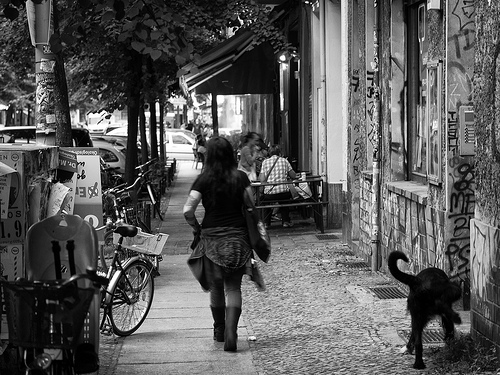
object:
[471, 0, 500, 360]
wall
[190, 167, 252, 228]
black shirt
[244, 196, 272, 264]
purse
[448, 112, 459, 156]
graffiti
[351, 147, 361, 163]
graffiti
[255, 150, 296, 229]
person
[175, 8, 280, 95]
awning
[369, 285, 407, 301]
drainage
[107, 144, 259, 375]
porch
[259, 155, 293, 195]
shirt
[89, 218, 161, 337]
bike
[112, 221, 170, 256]
basket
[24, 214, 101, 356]
seat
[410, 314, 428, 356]
leg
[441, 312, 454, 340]
leg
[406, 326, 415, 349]
leg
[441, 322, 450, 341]
leg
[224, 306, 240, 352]
boot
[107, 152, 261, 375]
sidewalk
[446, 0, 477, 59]
graffiti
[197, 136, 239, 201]
hair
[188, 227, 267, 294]
sweater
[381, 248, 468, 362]
dog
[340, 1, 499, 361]
building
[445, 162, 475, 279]
graffiti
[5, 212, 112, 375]
bikes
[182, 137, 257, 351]
woman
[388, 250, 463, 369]
black animal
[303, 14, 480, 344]
wall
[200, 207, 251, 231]
waist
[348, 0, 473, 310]
wall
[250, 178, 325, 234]
picnic table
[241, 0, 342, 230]
building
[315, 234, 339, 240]
grate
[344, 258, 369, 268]
grate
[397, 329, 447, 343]
grate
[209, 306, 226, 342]
boot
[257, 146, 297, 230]
woman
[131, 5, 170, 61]
leaves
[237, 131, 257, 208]
person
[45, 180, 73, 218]
sign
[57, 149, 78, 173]
sign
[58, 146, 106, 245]
sign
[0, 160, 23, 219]
sign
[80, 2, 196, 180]
shade tree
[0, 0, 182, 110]
shade tree